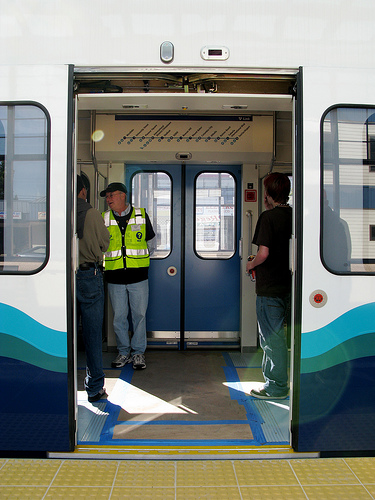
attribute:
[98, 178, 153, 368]
man — standing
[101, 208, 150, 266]
vest — yellow, reflective, safety, green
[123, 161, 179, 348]
door — closed, blue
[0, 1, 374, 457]
train — subway, passenger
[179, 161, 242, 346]
door — closed, blue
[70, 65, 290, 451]
doorway — open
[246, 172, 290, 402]
man — standing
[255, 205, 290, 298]
shirt — black, tee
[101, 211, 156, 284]
shirt — black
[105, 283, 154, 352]
jeans — blue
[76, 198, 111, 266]
shirt — grey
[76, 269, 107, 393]
jeans — blue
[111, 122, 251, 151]
guide — route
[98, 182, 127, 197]
cap — black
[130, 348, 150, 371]
shoe — black, white, tennis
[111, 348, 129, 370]
shoe — black, white, tennis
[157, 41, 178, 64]
light — white, grey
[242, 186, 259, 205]
alarm — red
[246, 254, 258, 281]
drink — canned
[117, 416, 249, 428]
line — blue, painted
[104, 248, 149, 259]
line — reflective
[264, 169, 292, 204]
hair — dark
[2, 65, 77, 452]
door — open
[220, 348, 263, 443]
line — blue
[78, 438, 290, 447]
line — blue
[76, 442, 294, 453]
doorstep — yellow